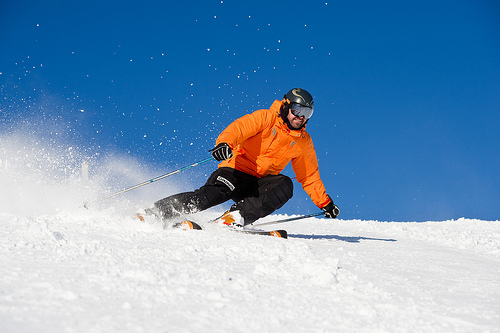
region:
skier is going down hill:
[126, 74, 350, 247]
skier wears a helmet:
[274, 82, 324, 142]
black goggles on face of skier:
[267, 82, 325, 135]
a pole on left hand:
[258, 193, 348, 240]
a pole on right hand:
[74, 144, 236, 213]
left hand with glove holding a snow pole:
[312, 193, 352, 228]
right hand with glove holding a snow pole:
[195, 130, 238, 178]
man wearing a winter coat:
[186, 76, 346, 233]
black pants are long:
[145, 165, 297, 230]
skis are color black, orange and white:
[116, 213, 293, 245]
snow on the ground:
[2, 215, 489, 331]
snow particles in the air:
[5, 15, 192, 164]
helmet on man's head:
[278, 84, 319, 131]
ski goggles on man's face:
[287, 100, 314, 120]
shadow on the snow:
[276, 229, 398, 245]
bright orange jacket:
[213, 82, 338, 207]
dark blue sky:
[1, 0, 499, 86]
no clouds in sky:
[0, 4, 498, 77]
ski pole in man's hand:
[76, 145, 216, 210]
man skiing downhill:
[81, 82, 343, 250]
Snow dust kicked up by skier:
[1, 142, 81, 227]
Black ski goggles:
[286, 102, 315, 122]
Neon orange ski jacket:
[220, 110, 331, 183]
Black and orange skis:
[171, 213, 300, 247]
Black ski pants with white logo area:
[168, 168, 280, 234]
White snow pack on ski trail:
[284, 227, 476, 328]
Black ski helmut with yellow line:
[280, 82, 315, 112]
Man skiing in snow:
[181, 70, 341, 235]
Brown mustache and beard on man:
[285, 101, 306, 128]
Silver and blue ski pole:
[92, 140, 217, 210]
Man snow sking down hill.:
[111, 86, 400, 249]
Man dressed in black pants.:
[153, 168, 304, 229]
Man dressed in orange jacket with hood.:
[214, 100, 329, 212]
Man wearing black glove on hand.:
[208, 141, 240, 170]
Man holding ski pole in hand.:
[63, 140, 232, 213]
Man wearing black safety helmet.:
[281, 82, 318, 110]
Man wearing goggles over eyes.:
[283, 98, 326, 121]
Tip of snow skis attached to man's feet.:
[176, 217, 293, 252]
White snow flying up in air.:
[14, 103, 159, 243]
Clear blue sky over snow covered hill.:
[334, 21, 496, 188]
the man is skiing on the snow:
[79, 82, 348, 245]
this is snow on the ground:
[0, 214, 497, 326]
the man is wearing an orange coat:
[203, 93, 334, 208]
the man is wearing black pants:
[128, 160, 288, 237]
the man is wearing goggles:
[291, 103, 316, 122]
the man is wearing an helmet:
[286, 83, 316, 129]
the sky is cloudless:
[0, 1, 499, 221]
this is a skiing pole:
[70, 145, 246, 211]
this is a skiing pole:
[225, 195, 345, 225]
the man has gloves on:
[206, 137, 361, 224]